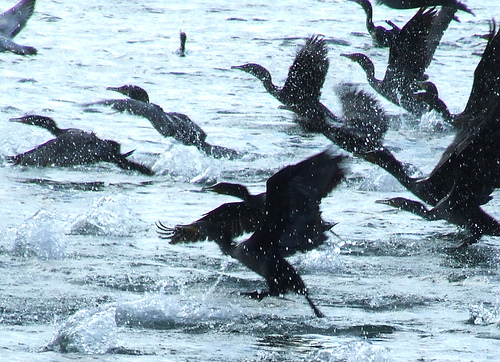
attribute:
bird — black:
[153, 142, 350, 316]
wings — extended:
[385, 5, 447, 95]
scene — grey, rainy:
[1, 0, 498, 360]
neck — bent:
[407, 191, 451, 221]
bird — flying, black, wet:
[0, 0, 37, 64]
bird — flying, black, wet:
[8, 115, 153, 177]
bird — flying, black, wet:
[103, 86, 237, 158]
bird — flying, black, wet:
[192, 226, 328, 318]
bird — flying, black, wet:
[160, 147, 350, 256]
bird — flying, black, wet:
[229, 33, 341, 123]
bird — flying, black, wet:
[303, 82, 417, 188]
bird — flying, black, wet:
[373, 164, 498, 249]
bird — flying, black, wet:
[359, 92, 499, 208]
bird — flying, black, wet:
[407, 26, 498, 130]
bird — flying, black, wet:
[341, 3, 461, 119]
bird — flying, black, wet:
[348, 2, 404, 46]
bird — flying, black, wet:
[373, 4, 463, 10]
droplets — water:
[415, 200, 425, 215]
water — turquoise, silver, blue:
[1, 1, 499, 360]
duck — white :
[163, 32, 217, 70]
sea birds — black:
[175, 144, 353, 308]